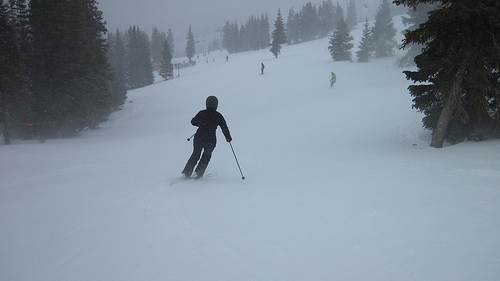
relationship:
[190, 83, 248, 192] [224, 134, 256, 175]
skier has ski pole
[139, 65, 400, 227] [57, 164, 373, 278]
snow on ground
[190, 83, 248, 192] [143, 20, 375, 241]
skier on ski slope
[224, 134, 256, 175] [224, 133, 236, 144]
ski pole in hand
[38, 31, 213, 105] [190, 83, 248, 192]
trees surround skier